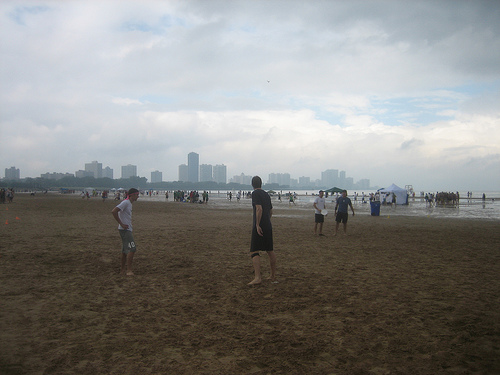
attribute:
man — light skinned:
[312, 190, 327, 237]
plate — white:
[321, 208, 329, 217]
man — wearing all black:
[246, 175, 277, 285]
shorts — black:
[249, 225, 275, 255]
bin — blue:
[370, 200, 381, 216]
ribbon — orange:
[126, 190, 139, 201]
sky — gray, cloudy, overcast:
[0, 0, 499, 191]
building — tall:
[188, 152, 200, 185]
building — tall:
[198, 163, 213, 185]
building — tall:
[213, 166, 226, 185]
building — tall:
[177, 162, 189, 183]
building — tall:
[121, 164, 136, 179]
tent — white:
[379, 181, 408, 204]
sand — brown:
[0, 190, 499, 374]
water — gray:
[154, 192, 499, 203]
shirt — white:
[113, 198, 135, 231]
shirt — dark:
[250, 189, 272, 230]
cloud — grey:
[256, 109, 498, 164]